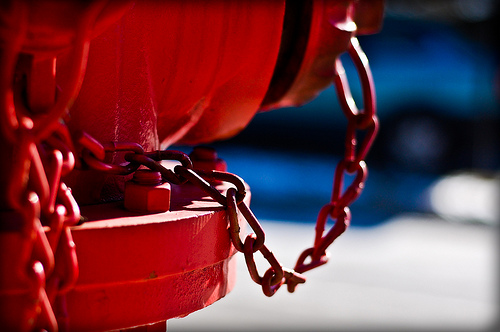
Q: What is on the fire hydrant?
A: The chain.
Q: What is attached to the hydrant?
A: Chains.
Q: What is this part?
A: Spout.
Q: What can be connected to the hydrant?
A: Hose.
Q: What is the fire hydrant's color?
A: Red.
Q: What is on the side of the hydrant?
A: Cap.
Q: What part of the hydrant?
A: Base.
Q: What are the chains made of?
A: Metal.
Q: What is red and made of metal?
A: Fire hydrant.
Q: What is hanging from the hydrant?
A: Chain.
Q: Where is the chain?
A: On the hydrant.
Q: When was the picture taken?
A: Daytime.